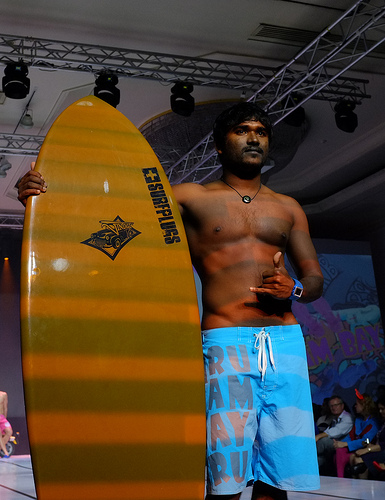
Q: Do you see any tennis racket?
A: No, there are no rackets.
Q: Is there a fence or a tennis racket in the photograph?
A: No, there are no rackets or fences.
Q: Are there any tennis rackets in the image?
A: No, there are no tennis rackets.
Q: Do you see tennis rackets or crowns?
A: No, there are no tennis rackets or crowns.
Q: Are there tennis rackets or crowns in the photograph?
A: No, there are no tennis rackets or crowns.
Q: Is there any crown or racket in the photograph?
A: No, there are no rackets or crowns.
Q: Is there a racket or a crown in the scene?
A: No, there are no rackets or crowns.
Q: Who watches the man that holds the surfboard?
A: The audience watches the man.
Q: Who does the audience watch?
A: The audience watches the man.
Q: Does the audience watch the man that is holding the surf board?
A: Yes, the audience watches the man.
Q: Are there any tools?
A: No, there are no tools.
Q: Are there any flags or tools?
A: No, there are no tools or flags.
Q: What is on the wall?
A: The graffiti is on the wall.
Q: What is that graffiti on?
A: The graffiti is on the wall.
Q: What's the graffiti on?
A: The graffiti is on the wall.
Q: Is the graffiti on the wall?
A: Yes, the graffiti is on the wall.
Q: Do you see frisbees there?
A: No, there are no frisbees.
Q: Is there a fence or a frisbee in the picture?
A: No, there are no frisbees or fences.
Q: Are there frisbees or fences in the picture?
A: No, there are no frisbees or fences.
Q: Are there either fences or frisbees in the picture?
A: No, there are no frisbees or fences.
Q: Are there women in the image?
A: No, there are no women.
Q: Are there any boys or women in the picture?
A: No, there are no women or boys.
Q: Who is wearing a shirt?
A: The man is wearing a shirt.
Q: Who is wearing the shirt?
A: The man is wearing a shirt.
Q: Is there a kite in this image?
A: No, there are no kites.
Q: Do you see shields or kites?
A: No, there are no kites or shields.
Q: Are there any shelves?
A: No, there are no shelves.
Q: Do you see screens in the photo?
A: No, there are no screens.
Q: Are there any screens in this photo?
A: No, there are no screens.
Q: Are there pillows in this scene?
A: No, there are no pillows.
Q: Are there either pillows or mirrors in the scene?
A: No, there are no pillows or mirrors.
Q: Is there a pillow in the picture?
A: No, there are no pillows.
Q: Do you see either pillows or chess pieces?
A: No, there are no pillows or chess pieces.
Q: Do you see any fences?
A: No, there are no fences.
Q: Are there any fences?
A: No, there are no fences.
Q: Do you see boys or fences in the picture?
A: No, there are no fences or boys.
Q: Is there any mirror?
A: No, there are no mirrors.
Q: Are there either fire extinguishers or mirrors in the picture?
A: No, there are no mirrors or fire extinguishers.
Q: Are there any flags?
A: No, there are no flags.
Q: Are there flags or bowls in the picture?
A: No, there are no flags or bowls.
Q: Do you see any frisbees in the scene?
A: No, there are no frisbees.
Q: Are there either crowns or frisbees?
A: No, there are no frisbees or crowns.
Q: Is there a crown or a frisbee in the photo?
A: No, there are no frisbees or crowns.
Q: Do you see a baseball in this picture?
A: No, there are no baseballs.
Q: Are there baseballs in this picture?
A: No, there are no baseballs.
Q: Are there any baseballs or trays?
A: No, there are no baseballs or trays.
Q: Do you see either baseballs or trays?
A: No, there are no baseballs or trays.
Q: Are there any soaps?
A: No, there are no soaps.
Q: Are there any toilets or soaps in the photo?
A: No, there are no soaps or toilets.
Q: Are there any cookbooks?
A: No, there are no cookbooks.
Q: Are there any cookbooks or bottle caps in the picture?
A: No, there are no cookbooks or bottle caps.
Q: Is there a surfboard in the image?
A: Yes, there is a surfboard.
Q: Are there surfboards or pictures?
A: Yes, there is a surfboard.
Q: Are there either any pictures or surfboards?
A: Yes, there is a surfboard.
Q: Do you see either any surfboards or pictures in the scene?
A: Yes, there is a surfboard.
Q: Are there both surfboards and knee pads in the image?
A: No, there is a surfboard but no knee pads.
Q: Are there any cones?
A: No, there are no cones.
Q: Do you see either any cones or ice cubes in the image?
A: No, there are no cones or ice cubes.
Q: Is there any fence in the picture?
A: No, there are no fences.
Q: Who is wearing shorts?
A: The man is wearing shorts.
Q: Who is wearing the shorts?
A: The man is wearing shorts.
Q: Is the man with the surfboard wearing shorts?
A: Yes, the man is wearing shorts.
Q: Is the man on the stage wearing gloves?
A: No, the man is wearing shorts.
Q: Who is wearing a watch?
A: The man is wearing a watch.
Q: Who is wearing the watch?
A: The man is wearing a watch.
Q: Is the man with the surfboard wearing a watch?
A: Yes, the man is wearing a watch.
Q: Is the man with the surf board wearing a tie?
A: No, the man is wearing a watch.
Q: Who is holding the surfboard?
A: The man is holding the surf board.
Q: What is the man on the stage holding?
A: The man is holding the surfboard.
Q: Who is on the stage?
A: The man is on the stage.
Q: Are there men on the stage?
A: Yes, there is a man on the stage.